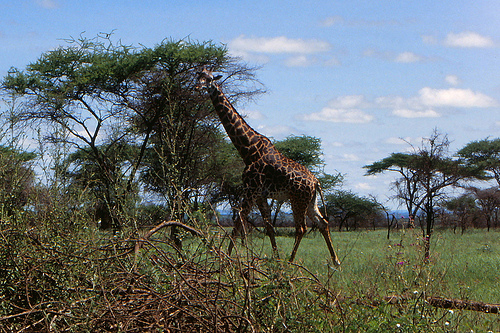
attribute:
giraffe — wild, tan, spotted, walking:
[194, 67, 343, 271]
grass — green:
[150, 229, 497, 325]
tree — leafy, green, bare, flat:
[1, 37, 228, 233]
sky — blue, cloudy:
[0, 2, 498, 198]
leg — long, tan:
[224, 189, 266, 268]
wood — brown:
[384, 293, 499, 316]